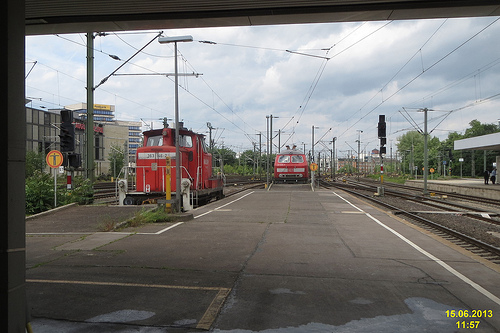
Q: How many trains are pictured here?
A: 2.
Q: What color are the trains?
A: Red.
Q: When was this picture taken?
A: Daytime.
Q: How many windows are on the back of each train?
A: 2.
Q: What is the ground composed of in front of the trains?
A: Pavement.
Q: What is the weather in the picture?
A: Overcast.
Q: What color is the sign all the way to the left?
A: Yellow and red.